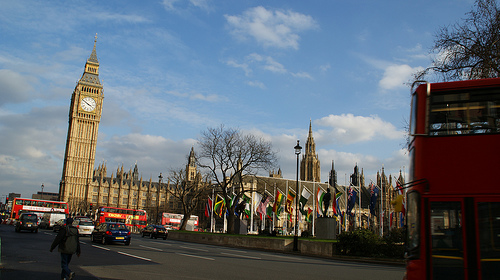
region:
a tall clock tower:
[56, 37, 105, 209]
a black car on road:
[87, 222, 129, 245]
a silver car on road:
[68, 217, 92, 235]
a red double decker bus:
[10, 195, 68, 222]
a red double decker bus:
[86, 203, 148, 230]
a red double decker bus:
[158, 210, 198, 230]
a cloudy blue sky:
[1, 0, 498, 198]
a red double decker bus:
[406, 82, 499, 278]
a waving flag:
[201, 192, 213, 219]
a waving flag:
[210, 193, 226, 215]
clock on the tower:
[70, 93, 111, 120]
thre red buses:
[22, 186, 212, 232]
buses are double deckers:
[2, 203, 184, 229]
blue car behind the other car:
[89, 218, 129, 235]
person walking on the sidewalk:
[41, 204, 82, 267]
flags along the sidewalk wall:
[197, 175, 413, 235]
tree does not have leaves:
[190, 115, 302, 190]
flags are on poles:
[211, 179, 403, 238]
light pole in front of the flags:
[285, 132, 310, 254]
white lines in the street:
[93, 242, 146, 263]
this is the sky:
[125, 33, 377, 107]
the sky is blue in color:
[156, 48, 224, 93]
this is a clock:
[78, 93, 101, 108]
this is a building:
[54, 118, 112, 180]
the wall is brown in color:
[70, 133, 90, 161]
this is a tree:
[203, 129, 260, 179]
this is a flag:
[298, 182, 325, 223]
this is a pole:
[288, 155, 306, 242]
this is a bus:
[413, 88, 498, 210]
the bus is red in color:
[444, 139, 486, 179]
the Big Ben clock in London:
[43, 29, 118, 221]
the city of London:
[12, 10, 429, 273]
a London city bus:
[383, 64, 494, 279]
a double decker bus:
[91, 205, 151, 235]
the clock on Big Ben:
[79, 93, 95, 115]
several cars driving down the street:
[15, 210, 136, 251]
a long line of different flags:
[201, 187, 408, 225]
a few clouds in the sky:
[115, 3, 408, 115]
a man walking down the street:
[43, 207, 86, 279]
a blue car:
[88, 220, 135, 246]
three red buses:
[38, 190, 212, 236]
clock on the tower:
[73, 88, 104, 108]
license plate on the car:
[109, 232, 131, 246]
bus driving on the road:
[390, 183, 475, 261]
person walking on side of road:
[49, 214, 87, 267]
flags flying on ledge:
[200, 185, 413, 254]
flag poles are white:
[296, 170, 304, 235]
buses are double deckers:
[18, 203, 66, 217]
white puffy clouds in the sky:
[213, 7, 317, 63]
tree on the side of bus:
[441, 21, 498, 126]